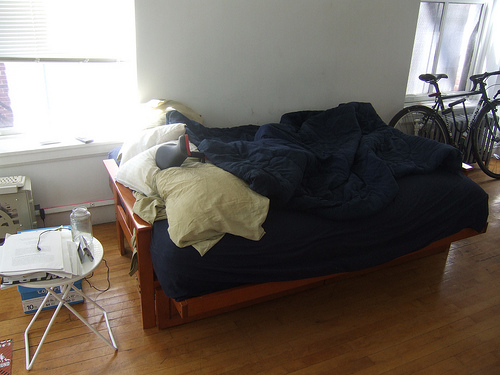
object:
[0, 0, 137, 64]
blind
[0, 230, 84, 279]
papers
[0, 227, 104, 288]
tabletop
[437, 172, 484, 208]
ground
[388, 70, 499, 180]
bicycle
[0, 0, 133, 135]
window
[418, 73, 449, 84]
seat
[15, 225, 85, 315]
box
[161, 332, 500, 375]
floor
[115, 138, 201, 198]
pillow cases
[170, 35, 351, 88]
brick wall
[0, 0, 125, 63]
white blinds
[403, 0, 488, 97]
window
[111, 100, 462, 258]
comforter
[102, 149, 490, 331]
bed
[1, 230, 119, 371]
small table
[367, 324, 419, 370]
wooden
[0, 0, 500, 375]
bedroom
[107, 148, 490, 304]
mattress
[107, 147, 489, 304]
sheets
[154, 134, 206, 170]
bike seat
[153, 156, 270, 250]
pillow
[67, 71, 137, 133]
sunlight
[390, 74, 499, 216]
inside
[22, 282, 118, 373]
metal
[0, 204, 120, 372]
stack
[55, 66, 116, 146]
up